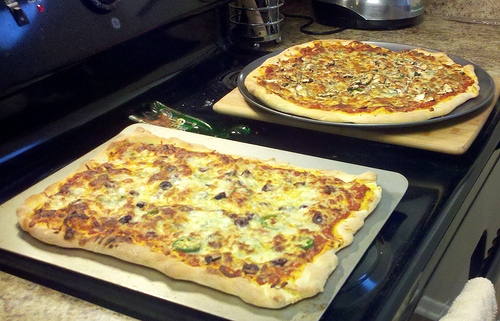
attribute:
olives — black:
[112, 199, 144, 224]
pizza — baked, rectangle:
[20, 125, 381, 312]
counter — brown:
[435, 19, 495, 59]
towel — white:
[432, 275, 499, 318]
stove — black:
[0, 45, 499, 317]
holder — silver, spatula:
[231, 0, 283, 50]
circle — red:
[33, 1, 42, 17]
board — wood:
[210, 77, 483, 164]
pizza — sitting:
[265, 17, 470, 134]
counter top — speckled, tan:
[0, 275, 137, 320]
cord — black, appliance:
[297, 26, 354, 38]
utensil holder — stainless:
[223, 1, 285, 48]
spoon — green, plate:
[149, 98, 249, 140]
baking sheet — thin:
[9, 134, 406, 318]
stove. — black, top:
[30, 14, 499, 319]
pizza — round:
[251, 23, 494, 126]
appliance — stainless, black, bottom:
[4, 2, 498, 310]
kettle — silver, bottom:
[353, 0, 421, 31]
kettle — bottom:
[308, 0, 430, 36]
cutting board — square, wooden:
[210, 27, 499, 155]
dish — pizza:
[2, 123, 408, 318]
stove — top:
[3, 5, 497, 316]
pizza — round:
[261, 30, 483, 125]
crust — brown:
[325, 103, 465, 126]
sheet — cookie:
[25, 107, 421, 317]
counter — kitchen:
[429, 9, 494, 58]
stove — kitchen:
[355, 127, 499, 304]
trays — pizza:
[16, 113, 383, 321]